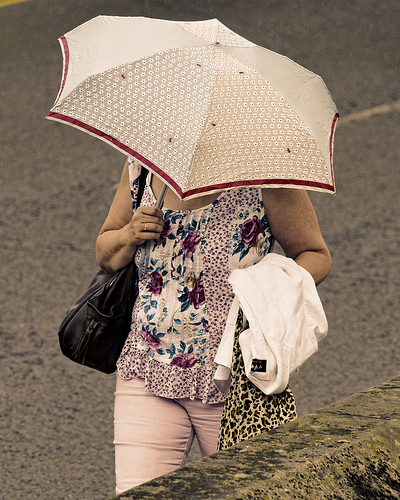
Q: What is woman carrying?
A: Purse.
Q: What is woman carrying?
A: Shirt.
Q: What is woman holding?
A: Umbrella.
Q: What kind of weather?
A: Rainy.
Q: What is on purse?
A: Zippers.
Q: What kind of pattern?
A: Floral.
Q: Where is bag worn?
A: Shoulder.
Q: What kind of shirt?
A: Jacket.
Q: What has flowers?
A: The blouse.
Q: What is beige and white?
A: The umbrella.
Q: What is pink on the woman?
A: Pants.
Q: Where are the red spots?
A: On the beige and red umbrella.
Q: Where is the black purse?
A: On the woman's side.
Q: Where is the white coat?
A: Over the woman's arm.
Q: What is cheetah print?
A: The coat.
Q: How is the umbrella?
A: Open.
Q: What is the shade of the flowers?
A: Pink.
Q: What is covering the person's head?
A: An umbrella.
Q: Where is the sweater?
A: Around the person's arm.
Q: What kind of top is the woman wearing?
A: Tank top.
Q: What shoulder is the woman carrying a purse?
A: Right shoulder.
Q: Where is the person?
A: On the street.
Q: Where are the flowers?
A: On the shirt.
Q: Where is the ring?
A: On the woman's right ring finger.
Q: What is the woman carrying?
A: An umbrella.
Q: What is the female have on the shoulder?
A: A purse.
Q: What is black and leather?
A: The purse.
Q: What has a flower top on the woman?
A: A blouse.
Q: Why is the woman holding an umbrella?
A: Raining.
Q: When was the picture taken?
A: Day time.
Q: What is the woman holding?
A: Umbrella.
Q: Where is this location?
A: Sidewalk.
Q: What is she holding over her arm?
A: Sweater.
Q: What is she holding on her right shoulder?
A: Bag.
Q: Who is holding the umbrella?
A: A woman.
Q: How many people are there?
A: One.